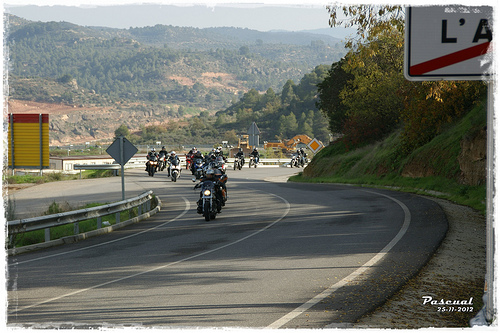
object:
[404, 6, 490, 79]
sign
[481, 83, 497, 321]
pole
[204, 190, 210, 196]
light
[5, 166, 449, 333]
road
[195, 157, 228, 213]
man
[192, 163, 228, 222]
bike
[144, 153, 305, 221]
motorcycles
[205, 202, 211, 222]
wheels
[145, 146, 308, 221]
crew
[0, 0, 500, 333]
valley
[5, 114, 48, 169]
sign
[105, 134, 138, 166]
sign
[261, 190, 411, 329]
lines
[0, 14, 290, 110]
hills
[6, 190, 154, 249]
barrier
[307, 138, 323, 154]
sign